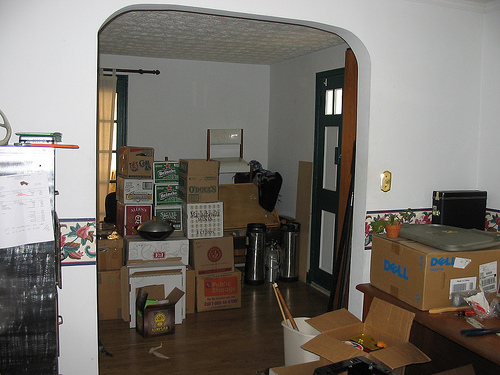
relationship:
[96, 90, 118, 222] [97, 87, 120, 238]
window on building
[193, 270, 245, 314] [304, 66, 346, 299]
box by door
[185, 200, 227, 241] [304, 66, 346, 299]
box by door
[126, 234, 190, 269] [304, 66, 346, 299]
box by door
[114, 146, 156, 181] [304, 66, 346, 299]
box by door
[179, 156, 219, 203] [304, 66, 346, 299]
box by door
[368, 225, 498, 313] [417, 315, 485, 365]
dell box on table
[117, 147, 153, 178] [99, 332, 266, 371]
box on floor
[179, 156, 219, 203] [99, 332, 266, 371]
box on floor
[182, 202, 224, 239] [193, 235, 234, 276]
box on box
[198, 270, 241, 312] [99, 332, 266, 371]
box on floor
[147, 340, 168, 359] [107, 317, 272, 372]
tape stuck to floor